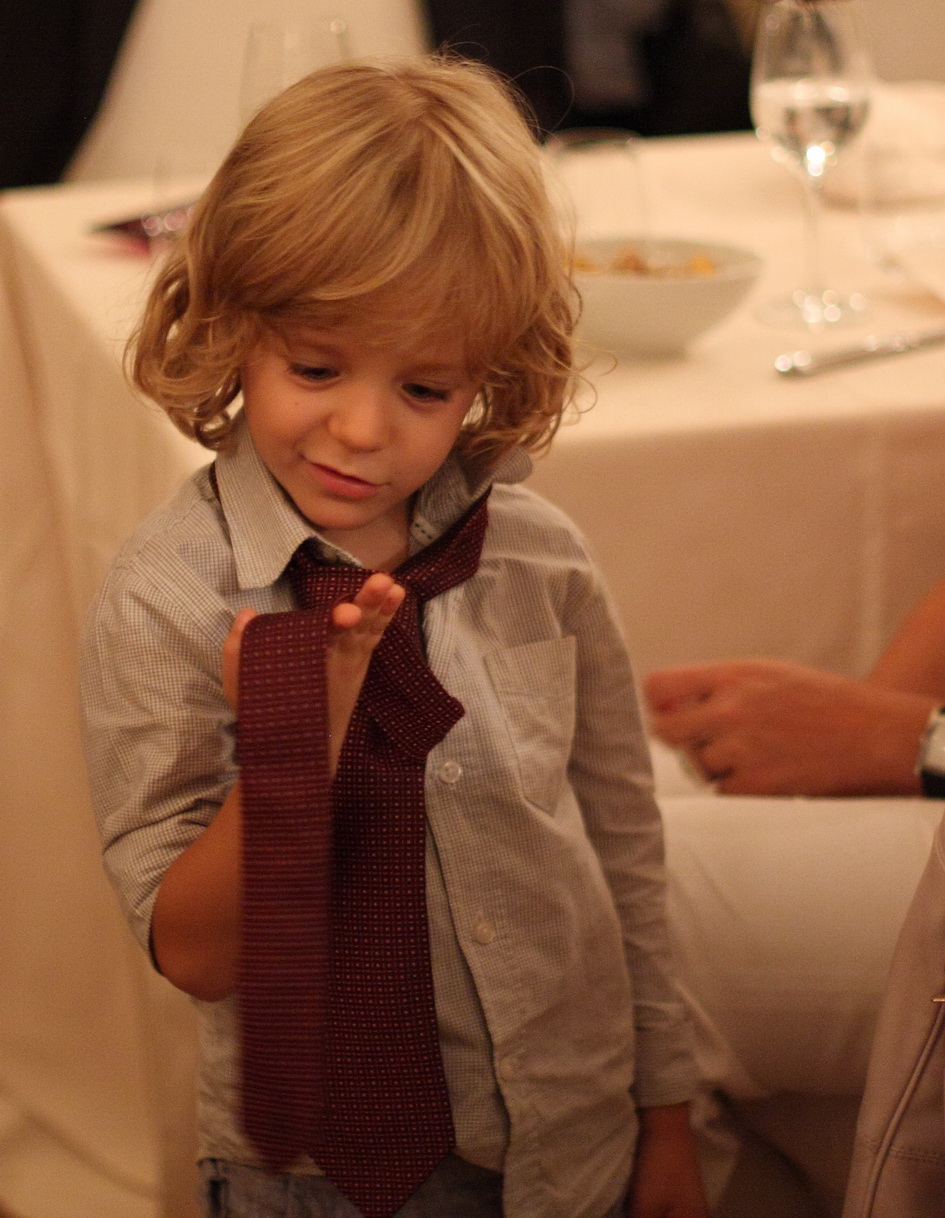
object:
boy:
[76, 22, 713, 1218]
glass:
[750, 0, 869, 335]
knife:
[775, 328, 945, 377]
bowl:
[567, 236, 760, 358]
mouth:
[299, 453, 391, 496]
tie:
[233, 482, 493, 1218]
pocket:
[483, 635, 578, 817]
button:
[439, 761, 461, 785]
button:
[475, 920, 492, 942]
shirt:
[79, 405, 698, 1218]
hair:
[105, 24, 620, 466]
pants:
[653, 793, 945, 1218]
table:
[0, 81, 945, 1217]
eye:
[398, 379, 452, 405]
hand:
[222, 572, 407, 756]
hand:
[627, 1102, 714, 1216]